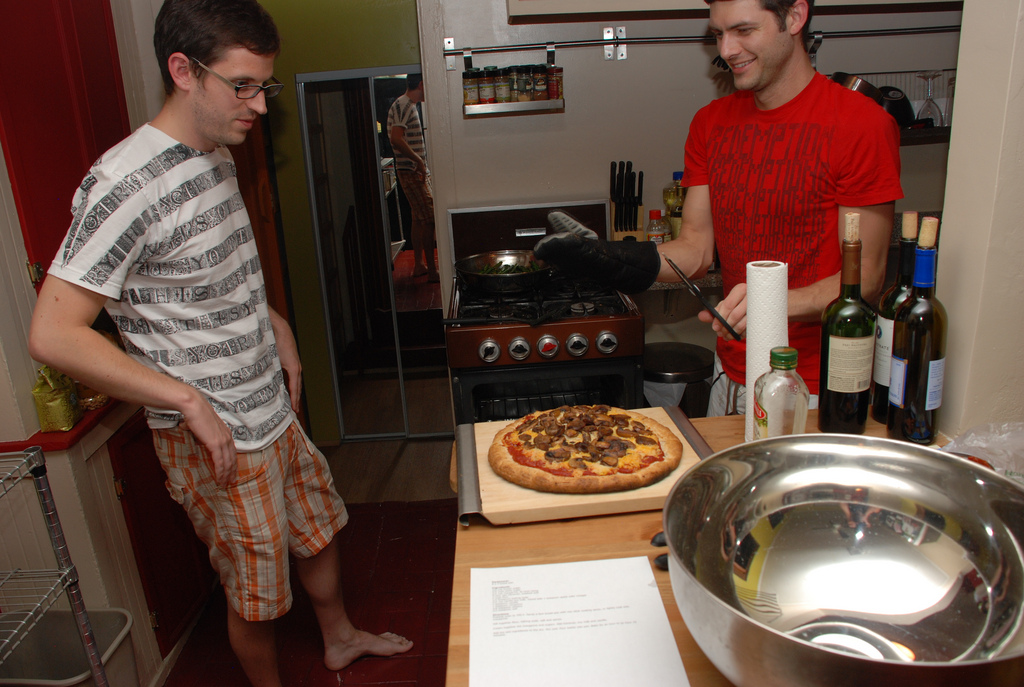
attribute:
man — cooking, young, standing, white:
[643, 15, 899, 315]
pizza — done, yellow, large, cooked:
[514, 408, 674, 473]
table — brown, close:
[483, 526, 618, 562]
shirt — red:
[717, 130, 888, 232]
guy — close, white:
[100, 44, 344, 503]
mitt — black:
[523, 200, 664, 299]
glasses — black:
[220, 69, 298, 108]